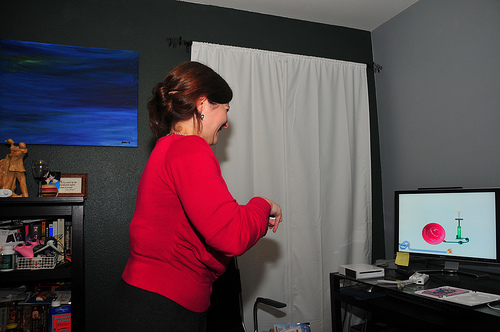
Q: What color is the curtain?
A: White.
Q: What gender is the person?
A: Female.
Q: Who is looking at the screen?
A: A woman.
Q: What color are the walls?
A: Gray.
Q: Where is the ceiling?
A: Above the woman.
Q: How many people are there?
A: One.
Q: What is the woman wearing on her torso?
A: A shirt.